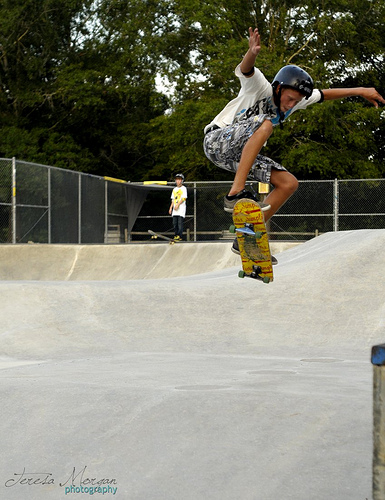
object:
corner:
[0, 457, 130, 499]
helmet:
[271, 65, 314, 112]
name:
[3, 462, 119, 494]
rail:
[368, 343, 385, 498]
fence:
[1, 153, 382, 244]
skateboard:
[227, 197, 273, 285]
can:
[102, 224, 121, 245]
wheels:
[253, 228, 264, 242]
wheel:
[227, 224, 238, 233]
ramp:
[0, 229, 384, 294]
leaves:
[53, 69, 80, 98]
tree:
[172, 1, 348, 180]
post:
[331, 175, 339, 232]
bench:
[217, 228, 237, 242]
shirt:
[203, 63, 323, 135]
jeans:
[170, 215, 184, 241]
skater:
[167, 173, 187, 244]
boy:
[201, 26, 385, 267]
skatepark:
[0, 228, 384, 499]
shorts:
[201, 111, 287, 187]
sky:
[69, 0, 118, 54]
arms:
[304, 86, 361, 107]